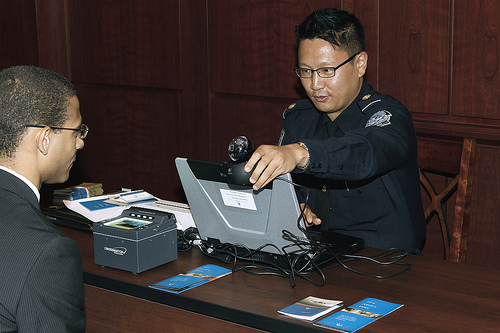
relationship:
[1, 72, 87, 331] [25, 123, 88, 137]
man wearing glasses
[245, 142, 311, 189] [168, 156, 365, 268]
hand on computer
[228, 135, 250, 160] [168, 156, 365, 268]
camera on computer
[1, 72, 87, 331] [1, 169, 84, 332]
man wearing suit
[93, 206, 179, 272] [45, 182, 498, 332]
box on desk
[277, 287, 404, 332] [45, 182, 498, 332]
pamphlets are on desk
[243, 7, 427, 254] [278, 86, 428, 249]
man in uniform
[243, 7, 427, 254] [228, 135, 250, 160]
man using camera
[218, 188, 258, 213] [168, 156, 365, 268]
label on computer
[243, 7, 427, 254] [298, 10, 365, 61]
man has dark hair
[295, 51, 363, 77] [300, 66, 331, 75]
eyeglasses on eyes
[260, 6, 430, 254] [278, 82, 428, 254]
man in shirt